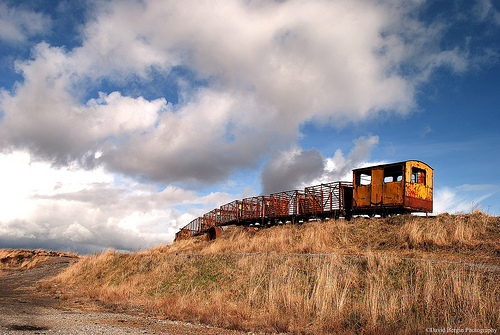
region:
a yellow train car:
[350, 159, 437, 211]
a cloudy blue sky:
[0, 0, 499, 252]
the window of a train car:
[357, 167, 373, 184]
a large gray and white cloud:
[0, 0, 475, 187]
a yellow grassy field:
[0, 202, 499, 334]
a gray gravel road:
[0, 255, 264, 334]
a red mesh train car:
[302, 177, 353, 220]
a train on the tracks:
[169, 157, 433, 243]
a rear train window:
[409, 165, 426, 189]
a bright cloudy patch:
[1, 147, 113, 224]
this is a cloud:
[76, 90, 174, 149]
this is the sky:
[450, 102, 482, 132]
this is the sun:
[3, 145, 59, 236]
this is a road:
[5, 251, 165, 333]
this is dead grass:
[206, 251, 357, 308]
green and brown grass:
[181, 250, 230, 286]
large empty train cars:
[176, 188, 338, 224]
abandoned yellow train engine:
[340, 142, 442, 221]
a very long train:
[132, 154, 460, 261]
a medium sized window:
[346, 159, 375, 187]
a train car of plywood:
[350, 156, 439, 213]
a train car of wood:
[352, 157, 439, 214]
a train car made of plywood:
[350, 160, 435, 215]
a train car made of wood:
[351, 160, 433, 214]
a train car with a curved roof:
[352, 157, 435, 214]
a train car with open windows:
[353, 157, 437, 214]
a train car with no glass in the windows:
[353, 156, 437, 216]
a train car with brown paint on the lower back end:
[350, 159, 433, 215]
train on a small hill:
[101, 141, 455, 333]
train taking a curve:
[160, 153, 442, 248]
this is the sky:
[427, 126, 474, 172]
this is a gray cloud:
[149, 100, 230, 178]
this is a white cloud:
[123, 228, 150, 245]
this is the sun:
[0, 152, 41, 211]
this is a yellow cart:
[344, 160, 453, 217]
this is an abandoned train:
[136, 158, 449, 241]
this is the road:
[2, 234, 237, 331]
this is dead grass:
[271, 257, 340, 295]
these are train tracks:
[141, 198, 499, 246]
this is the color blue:
[405, 114, 437, 154]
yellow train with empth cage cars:
[198, 151, 456, 228]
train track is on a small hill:
[145, 152, 495, 332]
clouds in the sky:
[5, 7, 453, 229]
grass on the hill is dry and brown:
[55, 214, 497, 334]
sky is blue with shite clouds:
[4, 5, 489, 179]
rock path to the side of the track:
[7, 245, 247, 333]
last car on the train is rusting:
[337, 148, 454, 218]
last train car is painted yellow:
[337, 128, 467, 240]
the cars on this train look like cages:
[166, 170, 381, 226]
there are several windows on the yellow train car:
[350, 161, 427, 211]